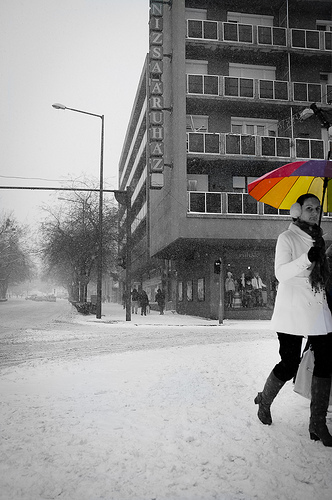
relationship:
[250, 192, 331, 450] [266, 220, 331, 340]
woman wears coat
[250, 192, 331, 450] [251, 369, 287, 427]
woman wears boot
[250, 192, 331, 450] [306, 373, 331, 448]
woman wears boot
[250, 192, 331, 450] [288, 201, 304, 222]
woman wears ear muff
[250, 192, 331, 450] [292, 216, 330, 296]
woman wears a scarf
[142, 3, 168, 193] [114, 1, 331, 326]
sign on building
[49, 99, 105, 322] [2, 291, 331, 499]
street light on street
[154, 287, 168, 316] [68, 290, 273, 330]
person on sidewalk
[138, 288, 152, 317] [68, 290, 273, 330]
person on sidewalk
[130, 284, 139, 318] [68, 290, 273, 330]
person on sidewalk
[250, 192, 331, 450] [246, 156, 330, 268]
woman carries umbrella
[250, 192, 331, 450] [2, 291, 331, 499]
woman crossing street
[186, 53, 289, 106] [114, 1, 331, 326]
balcony on building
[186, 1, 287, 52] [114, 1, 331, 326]
balcony on building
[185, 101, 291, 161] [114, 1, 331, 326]
balcony on building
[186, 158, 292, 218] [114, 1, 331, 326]
balcony on building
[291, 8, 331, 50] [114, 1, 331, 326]
balcony on building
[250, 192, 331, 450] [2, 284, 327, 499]
woman in snow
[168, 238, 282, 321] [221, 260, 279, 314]
store has window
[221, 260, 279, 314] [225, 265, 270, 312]
window has a mannequins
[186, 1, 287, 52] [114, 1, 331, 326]
balcony in building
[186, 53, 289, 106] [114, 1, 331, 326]
balcony in building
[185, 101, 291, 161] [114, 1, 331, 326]
balcony in building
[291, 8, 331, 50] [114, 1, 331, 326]
balcony in building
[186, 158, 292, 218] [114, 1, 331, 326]
balcony in building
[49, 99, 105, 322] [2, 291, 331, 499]
street light in street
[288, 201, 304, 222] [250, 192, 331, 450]
ear muff on woman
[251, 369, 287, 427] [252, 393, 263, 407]
boot has heel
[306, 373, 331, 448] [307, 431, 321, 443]
boot has heel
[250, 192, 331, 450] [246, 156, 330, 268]
woman holds umbrella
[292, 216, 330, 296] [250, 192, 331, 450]
scarf on woman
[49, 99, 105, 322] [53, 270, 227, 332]
street light on corner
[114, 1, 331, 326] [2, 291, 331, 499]
building on street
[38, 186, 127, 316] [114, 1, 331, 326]
tree next to building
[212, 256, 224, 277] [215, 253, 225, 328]
sign on a pole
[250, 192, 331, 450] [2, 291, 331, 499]
woman on street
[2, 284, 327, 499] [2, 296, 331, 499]
snow on ground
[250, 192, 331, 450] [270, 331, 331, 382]
woman wears pants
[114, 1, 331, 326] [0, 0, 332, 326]
building in in background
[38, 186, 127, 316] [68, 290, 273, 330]
tree on sidewalk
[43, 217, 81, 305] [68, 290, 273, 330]
tree on sidewalk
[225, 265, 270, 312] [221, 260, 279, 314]
mannequins are in shop window